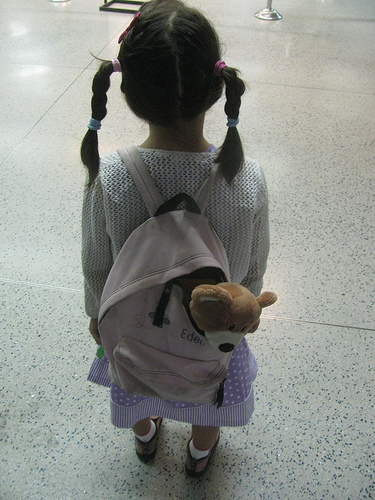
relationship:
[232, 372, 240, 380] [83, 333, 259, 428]
dot on skirt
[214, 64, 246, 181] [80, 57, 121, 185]
pig tails with pig tails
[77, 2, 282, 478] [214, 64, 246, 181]
girl with pig tails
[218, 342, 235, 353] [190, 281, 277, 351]
black nose of a bear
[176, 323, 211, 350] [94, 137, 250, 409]
name on a backpack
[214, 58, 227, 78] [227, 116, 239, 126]
hair tie in a hair tie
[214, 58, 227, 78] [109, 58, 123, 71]
hair tie in a hair tie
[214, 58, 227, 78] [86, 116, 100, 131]
hair tie in a hair tie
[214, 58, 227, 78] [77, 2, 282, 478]
hair tie in a girl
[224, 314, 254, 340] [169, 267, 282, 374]
eyes on a bear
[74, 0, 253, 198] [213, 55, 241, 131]
hair wrapped with bands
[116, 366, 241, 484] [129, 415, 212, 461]
feet in socks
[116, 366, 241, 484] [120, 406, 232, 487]
feet in shoes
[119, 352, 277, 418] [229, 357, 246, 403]
cloth with spots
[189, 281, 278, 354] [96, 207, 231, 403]
doll in backpack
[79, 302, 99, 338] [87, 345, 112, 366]
hand carrying green object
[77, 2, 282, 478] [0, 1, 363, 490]
girl standing on floor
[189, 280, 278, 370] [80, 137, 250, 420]
bear in bag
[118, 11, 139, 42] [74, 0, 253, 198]
clip in hair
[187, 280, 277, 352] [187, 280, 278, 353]
doll has head